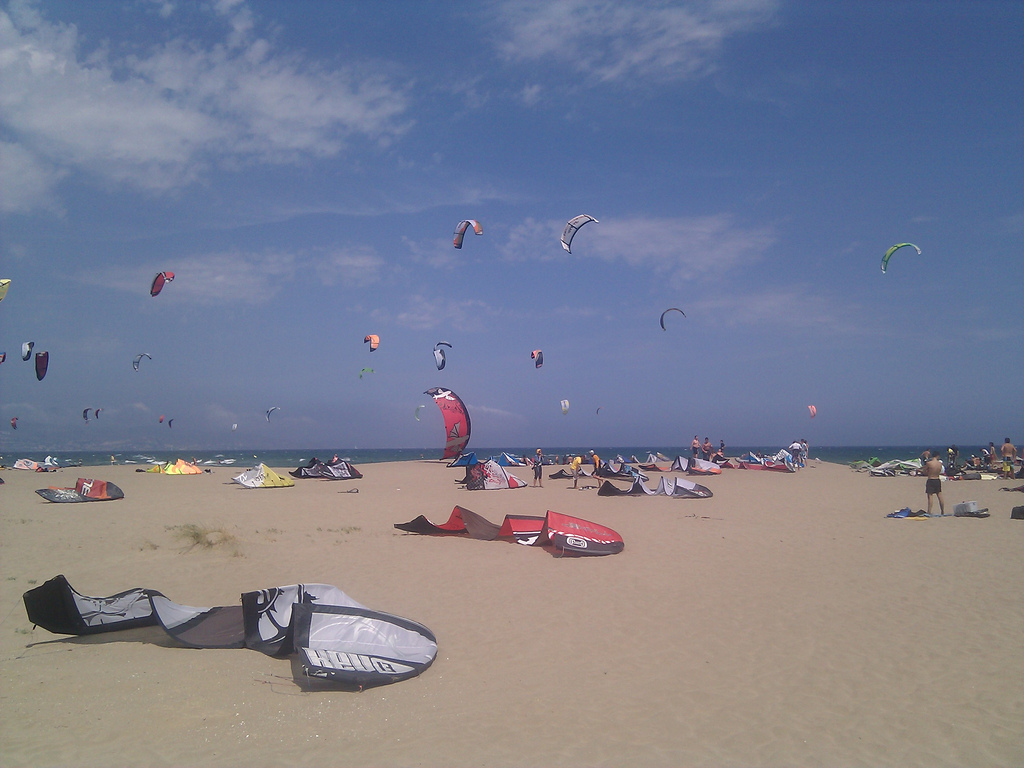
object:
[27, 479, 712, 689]
kites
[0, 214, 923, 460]
kites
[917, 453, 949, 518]
people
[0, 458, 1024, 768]
beach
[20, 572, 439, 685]
kite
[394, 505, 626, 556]
kite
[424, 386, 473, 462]
kite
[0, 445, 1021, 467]
ocean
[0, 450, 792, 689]
kites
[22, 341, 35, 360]
kite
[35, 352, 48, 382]
kite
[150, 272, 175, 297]
kite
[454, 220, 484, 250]
kite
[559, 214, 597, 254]
kite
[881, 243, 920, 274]
kite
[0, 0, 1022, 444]
sky